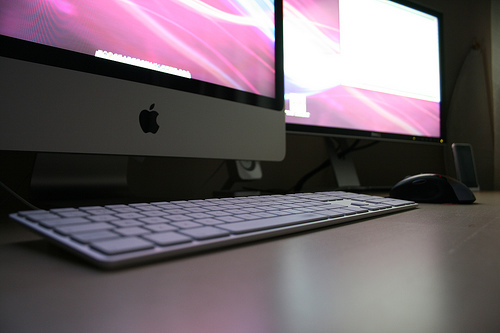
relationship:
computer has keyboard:
[0, 4, 288, 160] [14, 186, 422, 274]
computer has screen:
[0, 4, 288, 160] [276, 3, 448, 142]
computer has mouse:
[0, 4, 288, 160] [377, 172, 476, 207]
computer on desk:
[0, 4, 288, 160] [2, 184, 500, 328]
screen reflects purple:
[276, 3, 448, 142] [311, 94, 444, 135]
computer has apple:
[0, 4, 288, 160] [136, 107, 163, 136]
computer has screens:
[0, 4, 288, 160] [0, 1, 465, 164]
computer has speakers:
[0, 4, 288, 160] [452, 144, 477, 188]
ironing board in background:
[444, 36, 500, 189] [437, 4, 498, 46]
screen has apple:
[0, 4, 288, 160] [136, 107, 163, 136]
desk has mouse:
[2, 184, 500, 328] [377, 172, 476, 207]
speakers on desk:
[452, 144, 477, 188] [2, 184, 500, 328]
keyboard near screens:
[14, 186, 422, 274] [0, 1, 465, 164]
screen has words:
[276, 3, 448, 142] [341, 2, 439, 101]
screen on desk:
[276, 3, 448, 142] [2, 184, 500, 328]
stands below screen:
[317, 136, 403, 190] [276, 3, 448, 142]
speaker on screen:
[228, 161, 267, 180] [0, 4, 288, 160]